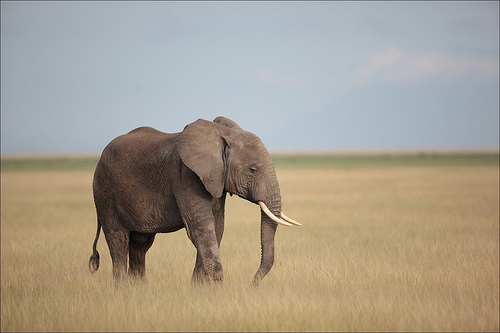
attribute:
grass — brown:
[2, 147, 498, 327]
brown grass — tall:
[2, 148, 499, 331]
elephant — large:
[82, 110, 305, 287]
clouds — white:
[346, 44, 495, 89]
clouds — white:
[238, 70, 285, 90]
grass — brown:
[326, 145, 416, 225]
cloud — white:
[357, 45, 496, 103]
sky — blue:
[2, 12, 319, 96]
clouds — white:
[270, 55, 359, 102]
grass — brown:
[8, 215, 80, 278]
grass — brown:
[0, 164, 496, 330]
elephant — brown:
[56, 103, 309, 303]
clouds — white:
[147, 35, 246, 102]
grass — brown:
[325, 255, 479, 327]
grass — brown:
[332, 182, 454, 219]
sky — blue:
[0, 0, 498, 150]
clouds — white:
[0, 2, 497, 159]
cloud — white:
[351, 42, 498, 89]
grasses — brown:
[308, 197, 481, 317]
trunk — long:
[252, 190, 281, 285]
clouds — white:
[355, 34, 462, 90]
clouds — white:
[324, 37, 483, 101]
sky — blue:
[74, 13, 436, 120]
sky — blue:
[84, 31, 420, 130]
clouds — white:
[329, 41, 477, 91]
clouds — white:
[262, 29, 489, 94]